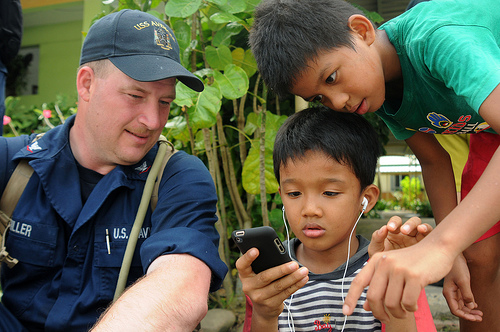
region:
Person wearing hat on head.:
[90, 16, 173, 78]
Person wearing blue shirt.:
[48, 248, 105, 297]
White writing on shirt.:
[101, 216, 175, 250]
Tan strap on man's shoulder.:
[3, 173, 30, 207]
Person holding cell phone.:
[238, 228, 283, 278]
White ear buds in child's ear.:
[353, 192, 375, 215]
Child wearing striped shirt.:
[311, 283, 341, 310]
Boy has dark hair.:
[272, 22, 306, 55]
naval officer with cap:
[4, 5, 236, 330]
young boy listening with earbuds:
[228, 101, 389, 329]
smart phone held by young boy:
[229, 225, 295, 275]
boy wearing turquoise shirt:
[247, 1, 499, 318]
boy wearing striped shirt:
[232, 102, 390, 330]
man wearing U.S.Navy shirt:
[2, 8, 229, 330]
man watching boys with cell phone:
[3, 5, 228, 329]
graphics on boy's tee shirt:
[403, 108, 492, 135]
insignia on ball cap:
[151, 25, 173, 52]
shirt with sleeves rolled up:
[1, 114, 231, 330]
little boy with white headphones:
[228, 98, 397, 285]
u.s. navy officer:
[33, 6, 283, 329]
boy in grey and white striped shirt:
[205, 108, 453, 325]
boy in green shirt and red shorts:
[221, 7, 498, 211]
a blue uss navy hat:
[48, 11, 237, 186]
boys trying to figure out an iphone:
[202, 4, 462, 318]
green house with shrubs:
[25, 5, 257, 190]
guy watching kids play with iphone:
[31, 4, 437, 284]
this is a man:
[0, 15, 234, 327]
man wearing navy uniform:
[2, 27, 224, 327]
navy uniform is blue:
[6, 107, 234, 324]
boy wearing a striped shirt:
[203, 222, 423, 330]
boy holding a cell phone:
[218, 200, 323, 318]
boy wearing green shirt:
[363, 0, 499, 162]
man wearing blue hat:
[71, 4, 206, 116]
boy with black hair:
[255, 101, 394, 198]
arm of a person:
[112, 248, 220, 328]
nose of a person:
[123, 106, 170, 134]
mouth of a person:
[116, 126, 173, 144]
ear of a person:
[60, 63, 115, 107]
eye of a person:
[286, 169, 360, 196]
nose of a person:
[300, 205, 337, 219]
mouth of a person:
[289, 219, 336, 240]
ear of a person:
[350, 181, 391, 228]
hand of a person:
[316, 238, 443, 328]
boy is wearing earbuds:
[267, 122, 370, 330]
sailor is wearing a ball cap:
[78, 8, 204, 91]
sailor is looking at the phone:
[59, 9, 193, 171]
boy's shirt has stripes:
[266, 234, 400, 330]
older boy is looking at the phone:
[242, 7, 393, 120]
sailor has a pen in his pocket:
[94, 221, 124, 262]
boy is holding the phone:
[225, 218, 314, 330]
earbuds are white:
[274, 195, 373, 330]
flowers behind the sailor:
[5, 100, 55, 131]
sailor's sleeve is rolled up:
[132, 222, 231, 288]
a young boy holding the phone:
[228, 107, 433, 328]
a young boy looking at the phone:
[250, 0, 497, 328]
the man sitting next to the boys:
[0, 8, 226, 330]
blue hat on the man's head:
[78, 7, 204, 93]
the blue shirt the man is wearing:
[1, 115, 228, 330]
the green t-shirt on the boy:
[376, 0, 499, 140]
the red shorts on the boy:
[460, 130, 499, 244]